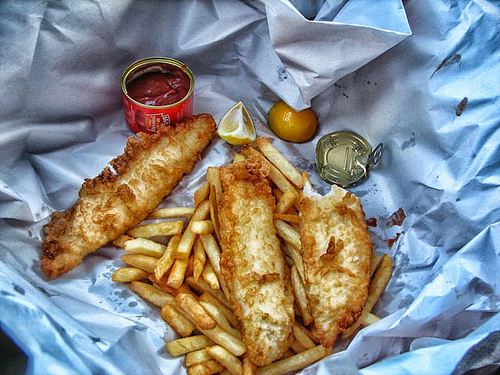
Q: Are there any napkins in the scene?
A: No, there are no napkins.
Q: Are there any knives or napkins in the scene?
A: No, there are no napkins or knives.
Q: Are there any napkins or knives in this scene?
A: No, there are no napkins or knives.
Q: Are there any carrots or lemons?
A: Yes, there is a lemon.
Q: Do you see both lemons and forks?
A: No, there is a lemon but no forks.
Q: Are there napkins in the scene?
A: No, there are no napkins.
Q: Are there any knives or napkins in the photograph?
A: No, there are no napkins or knives.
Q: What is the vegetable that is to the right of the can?
A: The vegetable is a lemon.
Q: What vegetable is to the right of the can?
A: The vegetable is a lemon.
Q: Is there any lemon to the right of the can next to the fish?
A: Yes, there is a lemon to the right of the can.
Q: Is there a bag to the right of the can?
A: No, there is a lemon to the right of the can.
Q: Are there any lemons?
A: Yes, there is a lemon.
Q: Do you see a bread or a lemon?
A: Yes, there is a lemon.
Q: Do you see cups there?
A: No, there are no cups.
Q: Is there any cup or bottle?
A: No, there are no cups or bottles.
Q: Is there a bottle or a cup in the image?
A: No, there are no cups or bottles.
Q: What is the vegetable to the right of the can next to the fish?
A: The vegetable is a lemon.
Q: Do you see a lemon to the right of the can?
A: Yes, there is a lemon to the right of the can.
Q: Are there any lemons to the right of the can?
A: Yes, there is a lemon to the right of the can.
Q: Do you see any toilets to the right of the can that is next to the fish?
A: No, there is a lemon to the right of the can.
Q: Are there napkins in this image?
A: No, there are no napkins.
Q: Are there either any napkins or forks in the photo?
A: No, there are no napkins or forks.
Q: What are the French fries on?
A: The French fries are on the fish.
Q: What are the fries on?
A: The French fries are on the fish.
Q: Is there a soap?
A: No, there are no soaps.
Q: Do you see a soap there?
A: No, there are no soaps.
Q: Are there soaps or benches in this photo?
A: No, there are no soaps or benches.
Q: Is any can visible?
A: Yes, there is a can.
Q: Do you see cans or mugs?
A: Yes, there is a can.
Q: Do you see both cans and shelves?
A: No, there is a can but no shelves.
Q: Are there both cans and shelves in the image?
A: No, there is a can but no shelves.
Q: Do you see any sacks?
A: No, there are no sacks.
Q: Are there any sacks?
A: No, there are no sacks.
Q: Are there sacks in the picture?
A: No, there are no sacks.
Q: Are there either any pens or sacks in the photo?
A: No, there are no sacks or pens.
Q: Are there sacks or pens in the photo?
A: No, there are no sacks or pens.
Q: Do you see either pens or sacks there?
A: No, there are no sacks or pens.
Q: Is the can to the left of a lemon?
A: Yes, the can is to the left of a lemon.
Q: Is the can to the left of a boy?
A: No, the can is to the left of a lemon.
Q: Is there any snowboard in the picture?
A: No, there are no snowboards.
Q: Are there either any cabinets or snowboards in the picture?
A: No, there are no snowboards or cabinets.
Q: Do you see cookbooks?
A: No, there are no cookbooks.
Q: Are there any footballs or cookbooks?
A: No, there are no cookbooks or footballs.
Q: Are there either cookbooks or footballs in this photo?
A: No, there are no cookbooks or footballs.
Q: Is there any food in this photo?
A: Yes, there is food.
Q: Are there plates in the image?
A: No, there are no plates.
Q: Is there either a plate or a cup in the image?
A: No, there are no plates or cups.